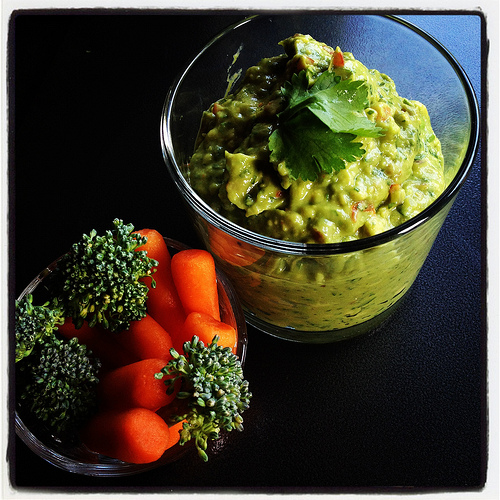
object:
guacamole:
[188, 34, 448, 336]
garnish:
[265, 68, 387, 181]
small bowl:
[13, 227, 249, 487]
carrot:
[88, 357, 175, 407]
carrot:
[131, 227, 186, 328]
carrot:
[170, 246, 225, 321]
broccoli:
[13, 325, 102, 443]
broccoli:
[156, 332, 253, 460]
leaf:
[270, 114, 360, 179]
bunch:
[0, 213, 255, 460]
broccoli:
[8, 292, 65, 367]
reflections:
[205, 221, 265, 271]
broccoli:
[54, 219, 160, 331]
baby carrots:
[87, 402, 169, 464]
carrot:
[129, 311, 174, 364]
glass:
[142, 17, 480, 347]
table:
[9, 14, 488, 500]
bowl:
[160, 9, 482, 346]